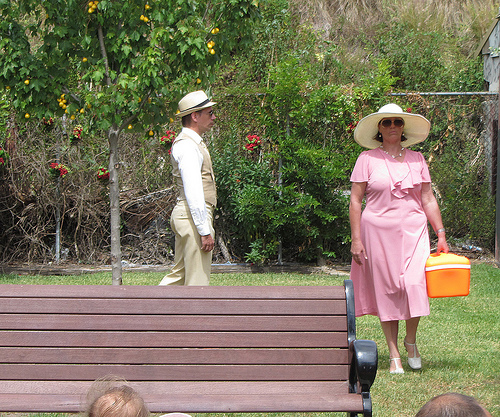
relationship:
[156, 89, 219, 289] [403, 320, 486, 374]
man on grass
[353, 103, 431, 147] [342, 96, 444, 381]
brim hat on woman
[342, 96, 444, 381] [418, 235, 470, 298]
woman carrying container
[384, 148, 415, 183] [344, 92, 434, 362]
bead necklace on woman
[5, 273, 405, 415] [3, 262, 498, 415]
bench on grass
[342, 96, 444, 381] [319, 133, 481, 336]
woman wearing dress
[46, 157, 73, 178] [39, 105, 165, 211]
flowers in bushes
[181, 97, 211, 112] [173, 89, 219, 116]
stripe on fedora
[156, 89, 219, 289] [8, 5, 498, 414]
man in park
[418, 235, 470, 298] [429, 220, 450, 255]
container in hand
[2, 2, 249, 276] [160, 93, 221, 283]
tree behind man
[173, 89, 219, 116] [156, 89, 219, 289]
fedora on man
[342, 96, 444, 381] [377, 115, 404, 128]
woman wearing sunglasses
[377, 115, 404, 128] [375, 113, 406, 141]
sunglasses on face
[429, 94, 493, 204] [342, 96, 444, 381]
chain fence behind woman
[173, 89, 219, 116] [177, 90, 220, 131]
fedora on head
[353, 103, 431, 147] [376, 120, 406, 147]
brim hat on head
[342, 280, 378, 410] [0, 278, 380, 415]
arm rest on bench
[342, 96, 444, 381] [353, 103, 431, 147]
woman wearing brim hat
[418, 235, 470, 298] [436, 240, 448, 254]
container in hand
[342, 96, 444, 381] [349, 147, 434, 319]
woman wearing dress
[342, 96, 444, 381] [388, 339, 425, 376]
woman wearing shoes